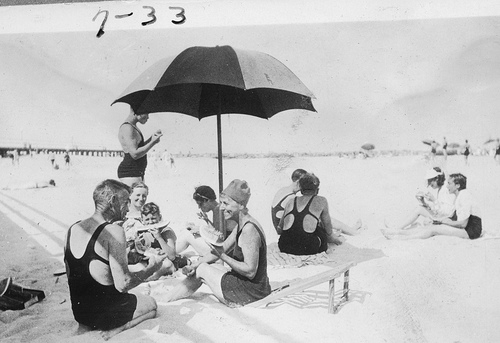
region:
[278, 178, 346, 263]
the back of the person in the sun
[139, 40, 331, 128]
a large umbrella on the beach provding shade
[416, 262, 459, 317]
sand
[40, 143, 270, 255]
people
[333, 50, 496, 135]
sky in the back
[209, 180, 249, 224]
woman smiling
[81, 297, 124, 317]
black cloth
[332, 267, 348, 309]
part of the bench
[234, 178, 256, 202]
swim cap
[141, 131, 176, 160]
arm of the man in the sun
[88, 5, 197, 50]
date written in ink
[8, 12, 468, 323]
black and white photo with white border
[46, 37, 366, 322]
people on a beach under an umbrella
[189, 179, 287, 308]
lady in an old fashioned swim suit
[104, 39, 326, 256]
striped umbrella in the sand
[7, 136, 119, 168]
wooden pier at the beach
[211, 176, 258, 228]
blonde on the beach in a swim cap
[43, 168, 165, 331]
man in an old fashioned swim suit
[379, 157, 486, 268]
couple of people on the beach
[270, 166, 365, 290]
sitting on a chair at the beach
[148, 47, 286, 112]
this is an umbrella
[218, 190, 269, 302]
this is a lady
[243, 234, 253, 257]
the lady is light skinned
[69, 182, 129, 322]
this is a man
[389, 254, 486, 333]
this is the ground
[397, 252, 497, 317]
the ground is bare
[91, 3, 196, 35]
this is a writing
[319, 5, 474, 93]
this is the sky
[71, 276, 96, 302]
this is a swimming costume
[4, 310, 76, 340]
this is a sandy area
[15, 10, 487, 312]
the picture is black and white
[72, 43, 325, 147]
the umbrella is more than one color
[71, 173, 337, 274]
the people are wearing bathing suits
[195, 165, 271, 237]
the woman is wearing a cap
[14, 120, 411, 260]
the people are on the beach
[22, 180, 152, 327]
the man is wearing a black bathing suit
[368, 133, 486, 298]
the two women are sitting on the sand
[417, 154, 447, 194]
woman wearing a white visor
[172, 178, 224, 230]
the woman is eating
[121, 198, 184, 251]
the boy is eating water melon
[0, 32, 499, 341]
The scene is black and white.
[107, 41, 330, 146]
The umbrella is open.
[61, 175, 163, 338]
Man is wearing old fashioned swinsuit.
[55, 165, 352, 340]
People are resting on the beach.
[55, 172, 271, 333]
Sitting on the beach and eating.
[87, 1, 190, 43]
Date on photo indicates it was taken in 1933.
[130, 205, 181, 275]
The boy is eating watermelon.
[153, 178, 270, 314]
Woman is wearing bathing suit.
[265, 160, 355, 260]
Boys have their backs to camera.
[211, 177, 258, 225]
Woman is wearing a bathing cap.